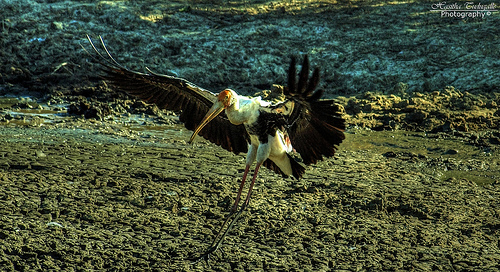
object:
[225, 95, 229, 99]
eye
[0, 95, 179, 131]
water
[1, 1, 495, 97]
slope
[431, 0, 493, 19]
lettering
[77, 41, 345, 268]
bird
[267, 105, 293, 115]
patch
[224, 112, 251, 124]
chest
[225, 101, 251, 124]
neck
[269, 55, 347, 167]
wing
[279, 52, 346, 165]
tail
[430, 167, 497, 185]
puddle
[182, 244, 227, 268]
grey feet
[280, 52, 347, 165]
feathers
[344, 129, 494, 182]
water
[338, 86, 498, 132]
rocky depression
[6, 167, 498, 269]
ground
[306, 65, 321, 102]
tail feather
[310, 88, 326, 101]
tail feather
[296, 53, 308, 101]
tail feather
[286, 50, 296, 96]
tail feather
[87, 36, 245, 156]
wing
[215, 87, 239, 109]
head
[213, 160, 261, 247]
leg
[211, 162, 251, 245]
leg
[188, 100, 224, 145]
beak